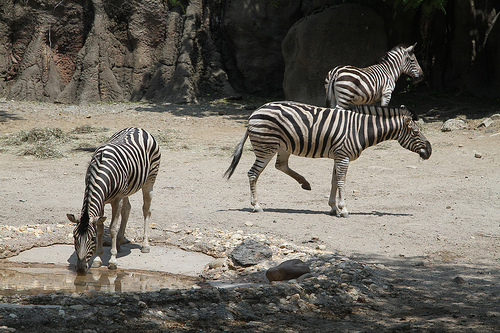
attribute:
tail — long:
[223, 132, 255, 182]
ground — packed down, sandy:
[3, 105, 499, 331]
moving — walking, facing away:
[322, 44, 428, 109]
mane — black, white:
[349, 102, 414, 119]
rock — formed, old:
[1, 2, 499, 115]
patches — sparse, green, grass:
[405, 84, 499, 141]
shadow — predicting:
[138, 0, 498, 128]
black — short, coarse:
[75, 171, 94, 236]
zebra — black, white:
[65, 38, 435, 285]